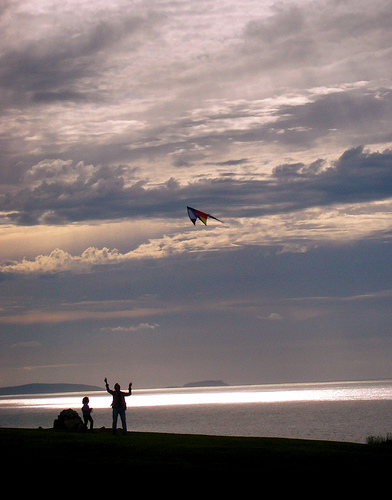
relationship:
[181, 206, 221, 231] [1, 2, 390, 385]
kite flying in sky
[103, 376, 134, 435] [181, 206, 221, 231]
person flying kite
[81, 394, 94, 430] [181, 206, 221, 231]
person flying kite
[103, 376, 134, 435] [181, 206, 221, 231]
person flying a kite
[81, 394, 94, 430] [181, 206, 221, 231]
person flying a kite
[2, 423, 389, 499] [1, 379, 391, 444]
hill over ocean water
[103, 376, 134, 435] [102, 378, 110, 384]
person has hand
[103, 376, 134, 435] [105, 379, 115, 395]
person has arm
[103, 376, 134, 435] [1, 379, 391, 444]
person standing at edge of ocean water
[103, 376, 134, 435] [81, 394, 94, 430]
person standing with person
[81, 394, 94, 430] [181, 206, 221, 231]
person watching flying kite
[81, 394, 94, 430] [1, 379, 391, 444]
person standing at edge of ocean water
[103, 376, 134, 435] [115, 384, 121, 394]
person has head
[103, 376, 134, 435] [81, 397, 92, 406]
person has head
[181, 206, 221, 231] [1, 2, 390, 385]
kite in sky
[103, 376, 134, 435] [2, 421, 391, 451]
person at beach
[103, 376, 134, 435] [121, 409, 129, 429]
person has leg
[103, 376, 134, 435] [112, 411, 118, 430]
person has leg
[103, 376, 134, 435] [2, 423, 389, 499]
person standing on hill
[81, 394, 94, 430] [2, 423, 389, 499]
person standing on hill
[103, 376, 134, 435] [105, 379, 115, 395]
person holding in air arm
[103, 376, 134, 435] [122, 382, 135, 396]
person holding in air arm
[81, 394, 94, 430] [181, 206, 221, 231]
person holding kite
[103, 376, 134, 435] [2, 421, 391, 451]
person standing on beach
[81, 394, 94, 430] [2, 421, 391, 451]
person standing on beach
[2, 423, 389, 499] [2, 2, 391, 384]
hill darkened by clouds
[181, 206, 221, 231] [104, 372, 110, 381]
kite has handle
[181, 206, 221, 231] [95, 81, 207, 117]
kite in sky